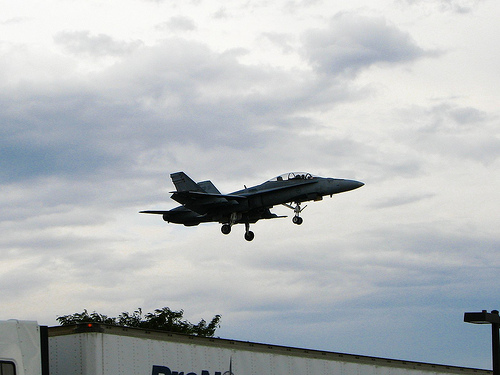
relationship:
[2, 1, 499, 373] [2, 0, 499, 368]
clouds in sky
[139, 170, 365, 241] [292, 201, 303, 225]
jet has landing gear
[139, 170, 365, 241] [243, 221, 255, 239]
jet has landing gear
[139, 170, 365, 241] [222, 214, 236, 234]
jet has landing gear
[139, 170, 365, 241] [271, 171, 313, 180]
jet has cockpit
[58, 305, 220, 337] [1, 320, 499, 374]
tree behind truck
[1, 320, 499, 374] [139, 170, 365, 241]
truck under jet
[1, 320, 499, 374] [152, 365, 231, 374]
truck has writing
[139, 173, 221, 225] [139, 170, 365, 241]
tail of jet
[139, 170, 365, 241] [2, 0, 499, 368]
jet in sky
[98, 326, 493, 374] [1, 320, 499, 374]
side of truck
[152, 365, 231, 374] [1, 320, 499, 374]
writing on truck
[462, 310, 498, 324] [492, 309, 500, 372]
light on light pole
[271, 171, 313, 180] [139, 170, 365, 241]
cockpit on jet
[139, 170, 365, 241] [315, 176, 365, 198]
jet has nose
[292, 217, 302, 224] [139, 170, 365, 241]
wheels on jet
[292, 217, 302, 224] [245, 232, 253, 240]
wheels on jet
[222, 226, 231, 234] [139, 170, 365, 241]
wheels on jet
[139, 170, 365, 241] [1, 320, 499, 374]
jet over truck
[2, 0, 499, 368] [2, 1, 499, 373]
sky has clouds